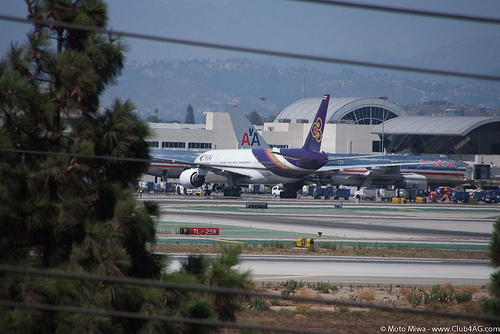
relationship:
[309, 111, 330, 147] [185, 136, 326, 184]
logo on plane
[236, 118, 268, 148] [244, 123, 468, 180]
logo on plane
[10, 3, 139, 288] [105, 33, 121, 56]
tree has needles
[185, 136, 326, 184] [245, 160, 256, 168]
plane has windows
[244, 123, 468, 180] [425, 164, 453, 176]
plane has windows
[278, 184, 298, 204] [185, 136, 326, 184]
wheels on plane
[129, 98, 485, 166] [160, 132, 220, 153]
building has windows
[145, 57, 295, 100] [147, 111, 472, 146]
mountain behind airport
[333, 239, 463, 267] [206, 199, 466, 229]
grass by runway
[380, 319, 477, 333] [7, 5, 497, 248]
writing on photo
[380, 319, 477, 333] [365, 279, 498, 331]
writing in corner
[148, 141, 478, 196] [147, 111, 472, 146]
airplanes at airport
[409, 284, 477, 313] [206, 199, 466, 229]
plants by runway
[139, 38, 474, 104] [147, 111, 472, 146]
mountains behind airport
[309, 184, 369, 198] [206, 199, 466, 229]
luggage on runway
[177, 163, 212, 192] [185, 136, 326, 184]
engine on plane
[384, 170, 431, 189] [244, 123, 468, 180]
engine on plane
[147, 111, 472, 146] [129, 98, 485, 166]
airport has terminal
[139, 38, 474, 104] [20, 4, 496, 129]
mountains in background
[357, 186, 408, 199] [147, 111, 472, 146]
vehicles by terminal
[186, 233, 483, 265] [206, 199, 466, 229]
ground by runway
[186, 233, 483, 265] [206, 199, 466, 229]
ground near runway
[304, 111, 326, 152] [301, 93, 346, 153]
design on tail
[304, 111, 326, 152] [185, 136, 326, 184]
design on airplane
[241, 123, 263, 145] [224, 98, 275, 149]
design on tail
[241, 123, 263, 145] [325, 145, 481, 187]
design on airplane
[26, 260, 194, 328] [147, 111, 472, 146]
fence around airport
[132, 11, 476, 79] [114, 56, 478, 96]
sky above hills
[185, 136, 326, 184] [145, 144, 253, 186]
plane has wings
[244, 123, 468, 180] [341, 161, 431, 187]
plane has wings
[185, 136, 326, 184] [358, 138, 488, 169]
plane at gate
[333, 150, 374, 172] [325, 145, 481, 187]
midsection of airplane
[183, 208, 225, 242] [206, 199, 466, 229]
sign on runway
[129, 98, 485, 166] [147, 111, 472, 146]
building at airport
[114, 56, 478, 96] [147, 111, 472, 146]
hills behind airport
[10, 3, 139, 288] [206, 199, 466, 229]
tree by runway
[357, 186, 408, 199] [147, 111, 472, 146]
vehicles at airport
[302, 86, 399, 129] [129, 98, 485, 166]
window at terminal